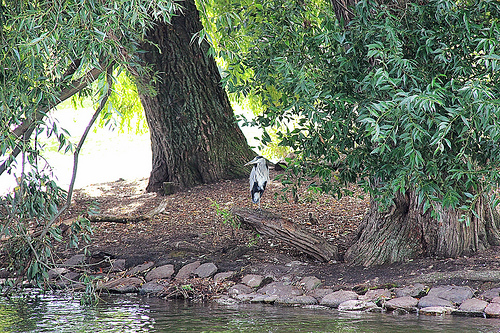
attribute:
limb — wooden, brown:
[232, 202, 339, 268]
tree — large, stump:
[368, 37, 471, 198]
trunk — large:
[123, 13, 254, 190]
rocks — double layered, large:
[17, 246, 499, 319]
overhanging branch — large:
[1, 43, 123, 308]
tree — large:
[109, 0, 270, 195]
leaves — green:
[2, 0, 183, 95]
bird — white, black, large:
[245, 154, 270, 211]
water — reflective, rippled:
[3, 287, 497, 329]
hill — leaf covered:
[26, 167, 377, 273]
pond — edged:
[0, 282, 499, 332]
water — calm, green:
[36, 300, 199, 332]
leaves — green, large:
[331, 78, 475, 205]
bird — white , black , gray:
[237, 152, 289, 215]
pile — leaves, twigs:
[156, 276, 228, 302]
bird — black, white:
[240, 150, 272, 207]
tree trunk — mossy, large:
[143, 144, 340, 229]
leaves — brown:
[173, 201, 204, 227]